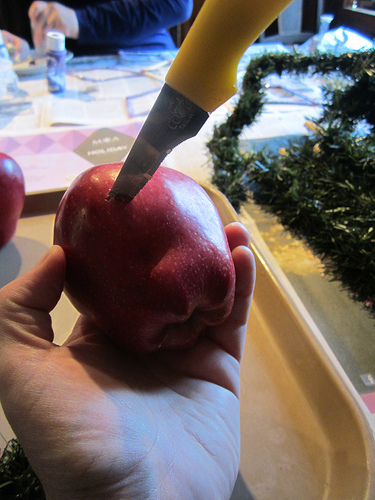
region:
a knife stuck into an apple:
[105, 0, 308, 208]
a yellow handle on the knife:
[163, 0, 297, 120]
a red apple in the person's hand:
[45, 153, 238, 360]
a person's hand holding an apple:
[0, 214, 265, 499]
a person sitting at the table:
[13, 0, 197, 58]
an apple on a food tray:
[0, 149, 28, 249]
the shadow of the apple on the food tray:
[0, 230, 52, 287]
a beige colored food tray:
[1, 168, 371, 498]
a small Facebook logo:
[358, 368, 373, 390]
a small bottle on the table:
[43, 30, 68, 96]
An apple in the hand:
[100, 220, 206, 299]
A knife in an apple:
[111, 190, 131, 198]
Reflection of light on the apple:
[184, 194, 205, 215]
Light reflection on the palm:
[150, 429, 205, 468]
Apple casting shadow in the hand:
[128, 364, 168, 377]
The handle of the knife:
[175, 69, 226, 87]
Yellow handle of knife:
[182, 57, 220, 89]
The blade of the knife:
[151, 168, 154, 171]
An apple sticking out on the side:
[0, 156, 12, 233]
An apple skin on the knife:
[144, 173, 150, 177]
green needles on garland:
[216, 50, 372, 307]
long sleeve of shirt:
[73, 0, 193, 50]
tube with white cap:
[46, 31, 65, 94]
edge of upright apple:
[0, 153, 24, 244]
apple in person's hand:
[0, 160, 253, 498]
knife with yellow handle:
[108, 0, 291, 199]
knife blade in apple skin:
[54, 83, 234, 347]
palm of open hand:
[67, 326, 238, 433]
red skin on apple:
[54, 161, 235, 349]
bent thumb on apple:
[0, 243, 75, 343]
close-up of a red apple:
[12, 12, 358, 406]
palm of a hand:
[45, 341, 261, 491]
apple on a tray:
[0, 140, 30, 248]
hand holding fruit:
[30, 155, 255, 370]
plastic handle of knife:
[165, 0, 288, 90]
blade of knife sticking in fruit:
[90, 84, 210, 206]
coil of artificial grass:
[248, 45, 368, 90]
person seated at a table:
[0, 0, 184, 63]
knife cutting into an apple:
[83, 0, 288, 210]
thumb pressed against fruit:
[0, 245, 75, 350]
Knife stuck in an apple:
[107, 0, 290, 199]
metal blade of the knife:
[109, 81, 205, 197]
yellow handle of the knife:
[161, 0, 287, 112]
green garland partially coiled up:
[204, 48, 370, 291]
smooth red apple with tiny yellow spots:
[50, 160, 231, 352]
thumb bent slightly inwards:
[0, 241, 63, 400]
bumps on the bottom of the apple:
[143, 276, 233, 353]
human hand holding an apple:
[0, 162, 256, 498]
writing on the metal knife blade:
[156, 93, 197, 133]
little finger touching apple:
[212, 246, 255, 353]